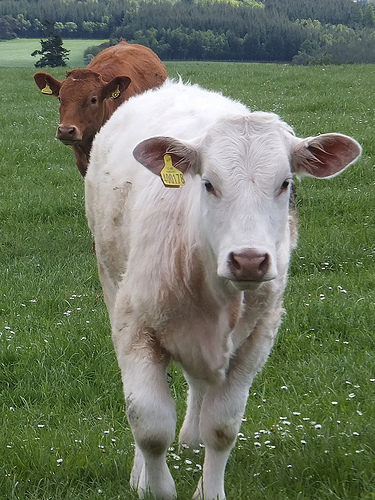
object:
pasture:
[0, 40, 375, 499]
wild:
[0, 39, 375, 499]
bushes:
[0, 0, 374, 64]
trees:
[0, 0, 375, 70]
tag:
[159, 155, 187, 189]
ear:
[131, 135, 203, 181]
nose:
[226, 248, 270, 281]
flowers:
[279, 383, 290, 393]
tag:
[39, 80, 53, 95]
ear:
[30, 71, 60, 96]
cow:
[32, 39, 168, 178]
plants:
[28, 27, 69, 69]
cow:
[83, 72, 363, 499]